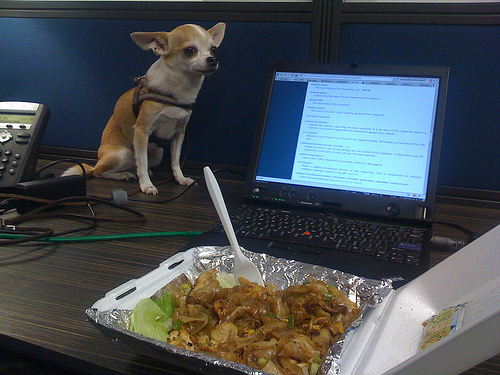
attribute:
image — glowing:
[296, 77, 435, 189]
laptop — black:
[177, 50, 456, 293]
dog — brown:
[59, 20, 226, 196]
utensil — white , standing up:
[199, 162, 276, 301]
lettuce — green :
[105, 287, 215, 355]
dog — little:
[89, 5, 228, 195]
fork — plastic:
[184, 159, 263, 282]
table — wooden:
[47, 259, 79, 322]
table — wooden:
[43, 271, 85, 326]